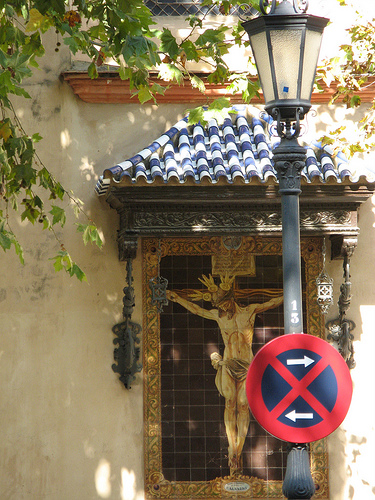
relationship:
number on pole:
[291, 313, 299, 324] [238, 6, 344, 497]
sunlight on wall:
[92, 455, 112, 498] [0, 0, 373, 499]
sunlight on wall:
[118, 465, 138, 499] [0, 0, 373, 499]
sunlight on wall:
[337, 302, 373, 498] [0, 0, 373, 499]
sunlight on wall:
[58, 125, 72, 150] [0, 0, 373, 499]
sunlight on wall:
[78, 154, 97, 180] [0, 0, 373, 499]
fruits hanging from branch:
[51, 25, 63, 58] [36, 2, 113, 68]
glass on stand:
[272, 31, 292, 70] [268, 110, 317, 485]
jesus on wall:
[165, 283, 283, 469] [0, 0, 373, 499]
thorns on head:
[186, 273, 234, 310] [206, 287, 237, 321]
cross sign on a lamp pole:
[246, 332, 354, 443] [238, 2, 329, 499]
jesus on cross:
[180, 281, 289, 427] [165, 259, 296, 473]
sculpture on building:
[144, 235, 326, 496] [1, 0, 373, 497]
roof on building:
[151, 3, 216, 11] [1, 0, 373, 497]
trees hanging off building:
[59, 13, 193, 57] [1, 0, 373, 497]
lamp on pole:
[242, 0, 328, 124] [275, 116, 315, 498]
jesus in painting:
[165, 283, 283, 469] [157, 248, 309, 415]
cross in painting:
[235, 280, 272, 299] [157, 248, 309, 415]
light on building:
[337, 305, 373, 497] [1, 0, 373, 497]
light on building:
[92, 455, 145, 498] [1, 0, 373, 497]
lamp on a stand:
[240, 25, 338, 128] [272, 137, 316, 497]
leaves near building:
[85, 20, 191, 103] [1, 0, 373, 497]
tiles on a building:
[101, 119, 372, 182] [1, 0, 373, 497]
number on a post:
[289, 299, 298, 323] [244, 4, 341, 493]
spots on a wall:
[13, 98, 192, 318] [0, 0, 373, 499]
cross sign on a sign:
[253, 337, 351, 440] [246, 333, 352, 443]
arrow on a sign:
[285, 355, 314, 366] [246, 333, 352, 443]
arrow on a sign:
[283, 409, 314, 421] [246, 333, 352, 443]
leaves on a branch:
[195, 27, 225, 43] [158, 19, 216, 77]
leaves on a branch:
[161, 25, 178, 59] [158, 19, 216, 77]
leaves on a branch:
[156, 57, 185, 82] [158, 19, 216, 77]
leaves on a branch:
[188, 70, 204, 94] [158, 19, 216, 77]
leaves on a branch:
[211, 61, 228, 78] [158, 19, 216, 77]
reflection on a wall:
[309, 124, 315, 139] [0, 0, 373, 499]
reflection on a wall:
[335, 106, 344, 120] [0, 0, 373, 499]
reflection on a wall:
[120, 468, 136, 498] [0, 0, 373, 499]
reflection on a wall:
[355, 304, 371, 422] [0, 0, 373, 499]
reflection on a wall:
[95, 459, 111, 496] [0, 0, 373, 499]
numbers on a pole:
[259, 290, 317, 342] [272, 135, 319, 497]